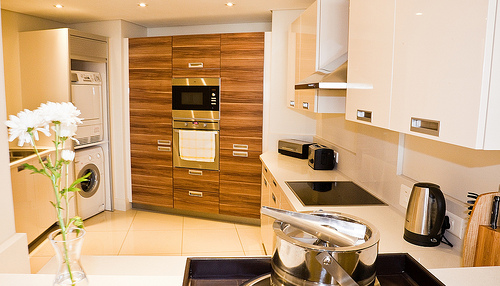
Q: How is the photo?
A: Clear.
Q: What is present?
A: Kitchenware.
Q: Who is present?
A: Nobody.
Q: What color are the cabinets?
A: White.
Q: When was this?
A: Daytime.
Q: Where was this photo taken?
A: In a kitchen.